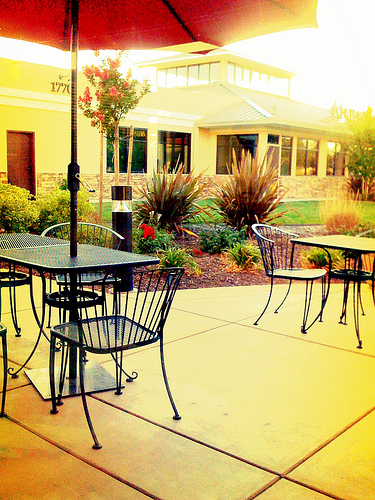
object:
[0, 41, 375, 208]
building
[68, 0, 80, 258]
black pole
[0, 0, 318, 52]
red umbrella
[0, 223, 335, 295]
mulch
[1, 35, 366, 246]
building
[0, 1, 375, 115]
sky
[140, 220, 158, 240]
flowers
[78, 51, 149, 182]
green trees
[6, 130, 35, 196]
door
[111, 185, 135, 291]
pole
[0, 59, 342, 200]
stone wall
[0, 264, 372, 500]
floor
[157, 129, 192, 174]
windows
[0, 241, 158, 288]
table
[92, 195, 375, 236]
grass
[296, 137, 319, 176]
window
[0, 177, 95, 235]
bush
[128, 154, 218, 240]
plant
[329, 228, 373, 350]
chairs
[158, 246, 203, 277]
plant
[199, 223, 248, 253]
plant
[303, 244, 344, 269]
plant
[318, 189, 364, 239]
plant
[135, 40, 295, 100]
balcony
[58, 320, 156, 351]
mesh wire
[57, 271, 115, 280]
mesh wire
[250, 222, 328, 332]
chair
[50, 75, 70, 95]
1770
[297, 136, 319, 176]
glass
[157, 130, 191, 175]
glass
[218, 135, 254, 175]
glass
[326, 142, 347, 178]
glass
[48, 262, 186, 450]
chair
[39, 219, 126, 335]
chair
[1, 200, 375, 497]
ground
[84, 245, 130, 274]
part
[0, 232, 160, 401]
table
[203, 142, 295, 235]
bush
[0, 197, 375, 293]
garden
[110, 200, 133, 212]
light